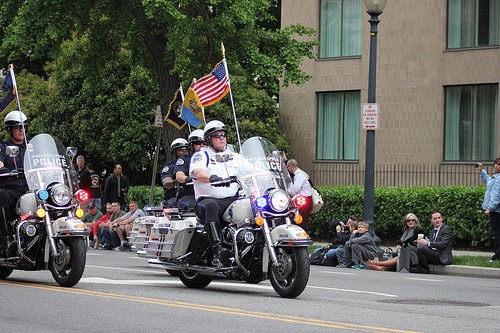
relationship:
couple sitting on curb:
[362, 206, 455, 274] [449, 263, 498, 276]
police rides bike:
[0, 110, 271, 266] [0, 129, 95, 286]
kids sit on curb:
[308, 221, 388, 267] [390, 256, 498, 281]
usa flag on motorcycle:
[189, 58, 238, 118] [125, 178, 338, 297]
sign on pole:
[361, 103, 378, 130] [349, 5, 389, 224]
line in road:
[348, 249, 462, 289] [0, 248, 500, 333]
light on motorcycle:
[288, 189, 310, 209] [90, 126, 350, 317]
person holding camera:
[471, 155, 499, 265] [471, 160, 482, 169]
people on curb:
[305, 209, 453, 273] [419, 262, 499, 282]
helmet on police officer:
[192, 115, 217, 134] [188, 115, 273, 256]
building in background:
[290, 23, 474, 140] [12, 6, 457, 95]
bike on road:
[0, 133, 91, 287] [91, 262, 185, 316]